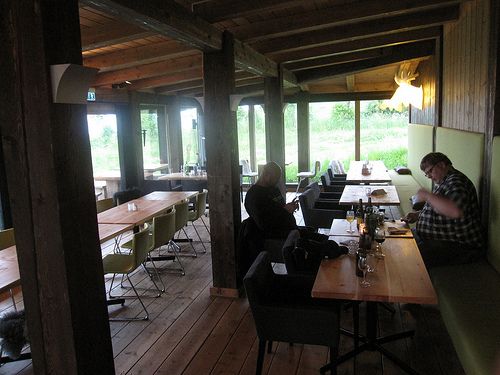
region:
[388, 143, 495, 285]
large man in an outdoor eating area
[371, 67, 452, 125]
light fixture on the wall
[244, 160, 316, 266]
man eating in an outdoor eating area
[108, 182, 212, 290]
table and chairs on the patio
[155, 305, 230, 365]
large wooden plank flooring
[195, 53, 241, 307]
thick wooden posts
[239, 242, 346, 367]
cloth backed chair for table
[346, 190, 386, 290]
line of wine glasses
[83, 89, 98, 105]
blue and white exit sign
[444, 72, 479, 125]
wood paneling in a restaurant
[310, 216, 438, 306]
a wooden furnished table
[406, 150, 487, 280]
a man in a checked shirt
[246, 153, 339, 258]
the man is looking through his phone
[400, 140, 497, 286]
the man is wearing spectacles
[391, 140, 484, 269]
the man is pouring himself a drink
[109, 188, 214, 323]
chars arranged in a row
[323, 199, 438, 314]
the table has several drinks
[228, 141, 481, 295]
the two men are sited opposite each other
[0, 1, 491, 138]
the room has wooden rafters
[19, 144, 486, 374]
the room has several empty chairs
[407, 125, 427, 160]
The headboards are green.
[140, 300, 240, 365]
The floor is wooden.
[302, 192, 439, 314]
The table is wooden.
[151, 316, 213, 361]
The floor is brown.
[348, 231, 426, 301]
The table is brown.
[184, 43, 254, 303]
There are wooden beams.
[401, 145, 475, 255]
The man is wearing plaid.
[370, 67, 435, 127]
The light is on.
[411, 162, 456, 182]
The man is wearing glasses.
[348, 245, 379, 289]
The glass is on the table.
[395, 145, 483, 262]
large man in a flannel shirt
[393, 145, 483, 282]
man pouring syrup in a restaurant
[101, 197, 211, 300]
row of plastic chairs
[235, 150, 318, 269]
balding man in a black shirt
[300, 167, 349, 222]
row of black cloth chairs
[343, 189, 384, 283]
row of wine glasses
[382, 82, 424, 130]
bright light fixture on the paneling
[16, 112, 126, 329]
dark wooden support post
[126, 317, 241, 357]
wide floor planks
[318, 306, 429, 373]
x style table legs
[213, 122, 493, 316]
two men at a table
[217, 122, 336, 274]
the bald man reads a menu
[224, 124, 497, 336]
the tables are made of wood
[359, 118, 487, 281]
the fat man sits at the booth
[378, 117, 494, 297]
the fat guy is wearing plaid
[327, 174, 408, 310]
glasses and beers on the table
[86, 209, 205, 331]
green plastic chairs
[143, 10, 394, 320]
this room has wooden beams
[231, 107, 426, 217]
grass outside the window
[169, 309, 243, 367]
wooden slatted flooring